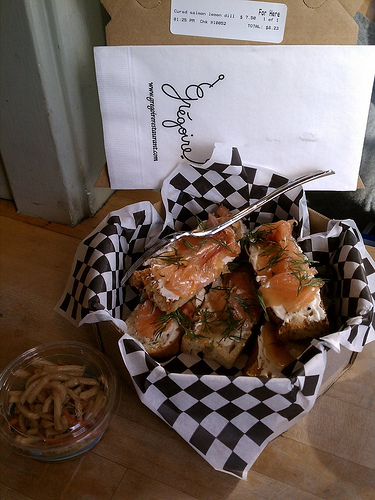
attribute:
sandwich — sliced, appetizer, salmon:
[246, 219, 329, 336]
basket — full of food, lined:
[110, 189, 364, 404]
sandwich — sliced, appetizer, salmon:
[183, 269, 260, 361]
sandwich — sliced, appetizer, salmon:
[135, 212, 252, 314]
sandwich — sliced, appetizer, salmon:
[126, 297, 179, 357]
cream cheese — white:
[271, 291, 325, 323]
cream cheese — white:
[156, 280, 181, 307]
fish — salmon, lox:
[250, 218, 325, 312]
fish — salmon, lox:
[156, 207, 241, 297]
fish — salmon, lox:
[208, 272, 261, 341]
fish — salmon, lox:
[138, 298, 169, 335]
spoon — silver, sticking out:
[120, 170, 340, 286]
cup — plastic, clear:
[0, 337, 117, 462]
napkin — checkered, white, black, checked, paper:
[52, 142, 374, 482]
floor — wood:
[0, 186, 375, 499]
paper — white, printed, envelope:
[91, 45, 375, 191]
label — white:
[169, 0, 287, 44]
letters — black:
[173, 8, 282, 31]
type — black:
[148, 73, 223, 164]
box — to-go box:
[100, 1, 374, 45]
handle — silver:
[211, 168, 335, 235]